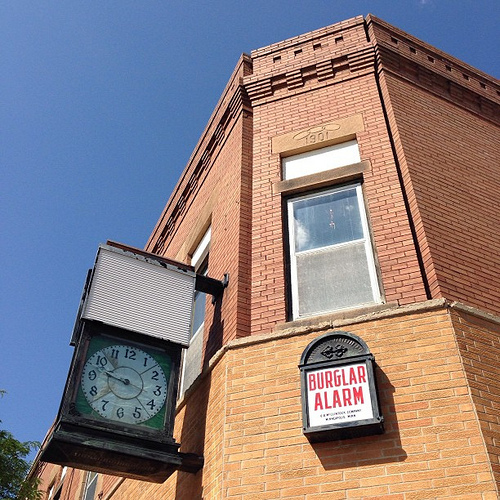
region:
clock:
[97, 344, 172, 440]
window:
[270, 185, 383, 310]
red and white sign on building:
[307, 355, 374, 410]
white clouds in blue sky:
[13, 19, 90, 89]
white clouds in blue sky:
[86, 5, 165, 83]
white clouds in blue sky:
[5, 180, 92, 236]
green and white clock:
[75, 330, 176, 430]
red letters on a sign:
[300, 365, 380, 425]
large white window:
[280, 190, 375, 310]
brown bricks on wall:
[340, 470, 415, 495]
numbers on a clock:
[85, 342, 170, 422]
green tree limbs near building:
[0, 426, 20, 493]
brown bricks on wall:
[437, 180, 477, 250]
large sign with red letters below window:
[296, 335, 387, 440]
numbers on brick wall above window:
[286, 115, 343, 141]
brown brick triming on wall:
[333, 25, 371, 76]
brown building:
[394, 312, 490, 462]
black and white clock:
[93, 321, 173, 438]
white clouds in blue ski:
[10, 13, 76, 80]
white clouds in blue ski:
[1, 240, 71, 341]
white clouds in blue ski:
[17, 175, 88, 240]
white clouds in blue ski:
[92, 105, 145, 172]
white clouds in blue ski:
[77, 37, 139, 107]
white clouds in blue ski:
[140, 45, 192, 113]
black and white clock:
[59, 349, 174, 421]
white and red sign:
[311, 352, 375, 459]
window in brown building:
[274, 177, 383, 314]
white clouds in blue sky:
[23, 36, 95, 96]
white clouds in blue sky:
[76, 28, 154, 105]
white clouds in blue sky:
[8, 261, 63, 338]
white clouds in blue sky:
[2, 137, 65, 218]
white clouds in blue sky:
[426, 8, 487, 49]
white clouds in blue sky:
[52, 138, 114, 202]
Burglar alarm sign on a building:
[269, 331, 387, 445]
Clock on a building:
[63, 315, 190, 444]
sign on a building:
[280, 333, 384, 452]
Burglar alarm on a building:
[283, 336, 375, 464]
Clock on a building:
[283, 337, 400, 455]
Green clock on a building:
[68, 323, 183, 460]